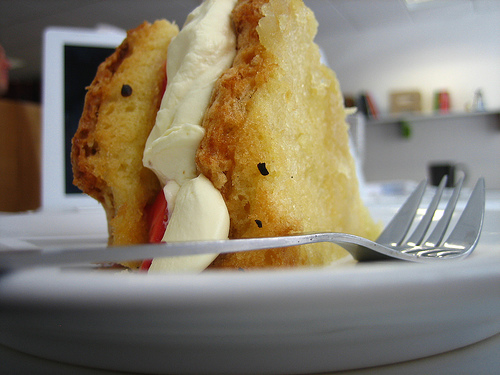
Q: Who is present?
A: No one.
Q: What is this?
A: Food.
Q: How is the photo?
A: Indoors.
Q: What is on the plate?
A: Food.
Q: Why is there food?
A: For eating.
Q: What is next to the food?
A: Fork.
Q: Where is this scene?
A: In the kitchen.